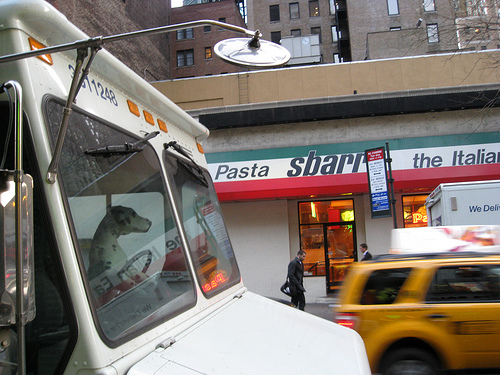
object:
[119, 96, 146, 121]
reflectors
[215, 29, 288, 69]
mirror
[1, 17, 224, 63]
pole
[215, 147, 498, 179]
words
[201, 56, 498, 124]
awning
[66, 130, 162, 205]
wipers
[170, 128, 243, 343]
windshield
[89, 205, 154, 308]
dog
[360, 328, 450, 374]
wheel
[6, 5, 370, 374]
truck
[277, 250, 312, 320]
man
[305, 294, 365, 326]
sidewalk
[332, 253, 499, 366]
cab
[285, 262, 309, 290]
coat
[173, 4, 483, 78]
buildings